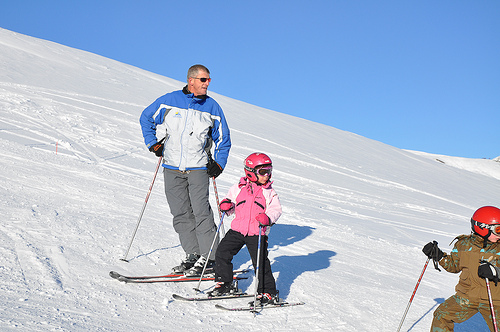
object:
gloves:
[420, 239, 498, 285]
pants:
[214, 230, 276, 296]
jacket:
[139, 86, 230, 171]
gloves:
[218, 198, 270, 228]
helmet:
[242, 151, 271, 183]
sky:
[0, 1, 499, 161]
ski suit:
[430, 231, 497, 330]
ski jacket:
[223, 176, 281, 234]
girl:
[212, 151, 281, 306]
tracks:
[0, 81, 498, 243]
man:
[137, 63, 231, 274]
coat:
[436, 233, 499, 291]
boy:
[422, 206, 499, 332]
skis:
[108, 269, 246, 285]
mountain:
[0, 25, 499, 331]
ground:
[0, 28, 496, 331]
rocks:
[436, 158, 445, 164]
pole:
[396, 258, 498, 331]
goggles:
[200, 77, 211, 83]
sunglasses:
[255, 166, 271, 176]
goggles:
[486, 225, 499, 237]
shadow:
[228, 221, 313, 268]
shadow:
[228, 247, 336, 305]